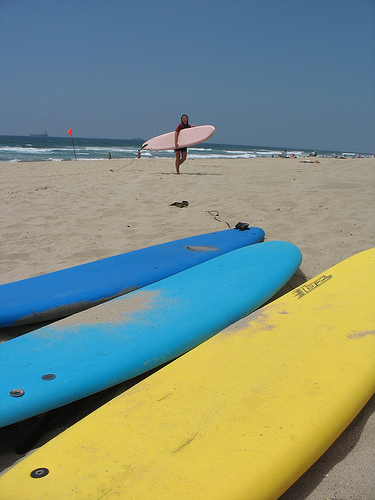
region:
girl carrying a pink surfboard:
[135, 109, 217, 174]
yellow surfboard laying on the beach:
[0, 238, 373, 495]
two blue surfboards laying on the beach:
[0, 222, 302, 425]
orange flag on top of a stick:
[67, 128, 77, 161]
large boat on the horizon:
[27, 129, 50, 139]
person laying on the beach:
[295, 158, 320, 163]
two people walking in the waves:
[105, 148, 146, 161]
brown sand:
[13, 178, 168, 233]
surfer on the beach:
[173, 113, 187, 177]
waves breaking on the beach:
[1, 143, 298, 160]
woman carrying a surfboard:
[96, 98, 224, 185]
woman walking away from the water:
[90, 94, 238, 187]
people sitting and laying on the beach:
[256, 141, 373, 178]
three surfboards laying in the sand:
[4, 208, 372, 498]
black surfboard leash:
[156, 186, 262, 234]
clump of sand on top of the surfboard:
[169, 236, 247, 264]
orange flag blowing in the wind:
[56, 118, 88, 172]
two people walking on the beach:
[102, 144, 151, 170]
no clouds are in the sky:
[2, 5, 373, 160]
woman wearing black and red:
[162, 106, 204, 190]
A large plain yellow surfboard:
[1, 246, 374, 498]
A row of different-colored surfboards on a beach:
[1, 223, 374, 497]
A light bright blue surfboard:
[0, 241, 310, 428]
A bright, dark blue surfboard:
[0, 227, 264, 327]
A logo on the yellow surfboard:
[294, 273, 334, 299]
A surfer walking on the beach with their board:
[139, 113, 214, 175]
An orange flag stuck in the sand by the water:
[65, 127, 76, 158]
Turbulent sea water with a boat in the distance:
[0, 130, 374, 158]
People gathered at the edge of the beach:
[271, 150, 371, 162]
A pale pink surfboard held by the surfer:
[141, 124, 214, 149]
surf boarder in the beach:
[109, 104, 243, 194]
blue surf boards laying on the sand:
[0, 216, 258, 326]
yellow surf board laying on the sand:
[291, 205, 372, 320]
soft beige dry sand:
[32, 210, 123, 245]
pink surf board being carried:
[133, 122, 229, 155]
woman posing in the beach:
[134, 109, 227, 190]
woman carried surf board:
[132, 110, 233, 181]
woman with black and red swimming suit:
[138, 117, 244, 186]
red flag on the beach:
[60, 120, 94, 185]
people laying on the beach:
[257, 140, 373, 181]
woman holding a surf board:
[127, 101, 228, 191]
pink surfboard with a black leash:
[70, 123, 225, 173]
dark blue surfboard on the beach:
[0, 214, 260, 334]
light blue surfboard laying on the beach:
[2, 221, 304, 429]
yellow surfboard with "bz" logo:
[1, 226, 372, 499]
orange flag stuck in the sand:
[61, 114, 89, 179]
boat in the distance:
[23, 127, 55, 143]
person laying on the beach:
[290, 153, 330, 178]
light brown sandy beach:
[1, 139, 373, 499]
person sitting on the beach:
[273, 143, 288, 164]